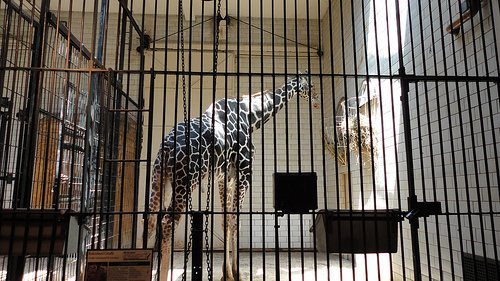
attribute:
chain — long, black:
[204, 2, 218, 278]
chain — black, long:
[179, 5, 193, 280]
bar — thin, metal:
[235, 0, 240, 279]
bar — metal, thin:
[247, 0, 254, 279]